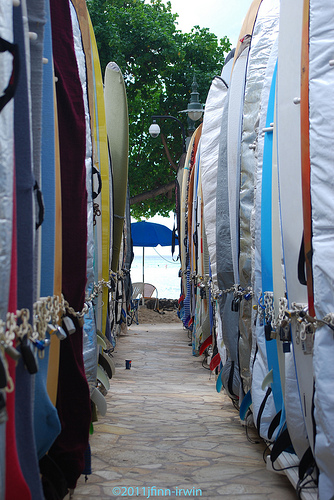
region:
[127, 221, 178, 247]
Blue beach umbrella.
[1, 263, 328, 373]
Locks locking the surfboards up.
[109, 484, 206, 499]
Copyright for jfinn-irwin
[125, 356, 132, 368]
A blue and red paper cup.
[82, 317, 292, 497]
A light stone walk way.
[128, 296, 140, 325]
A small blue chair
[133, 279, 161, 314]
Two beach chairs.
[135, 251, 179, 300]
The water of either an ocean or bay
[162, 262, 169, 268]
A person out in the water.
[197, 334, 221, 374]
Two red surfboard fins.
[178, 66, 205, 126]
Light above surfboard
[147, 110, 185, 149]
Security camera near blue umbrella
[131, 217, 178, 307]
Blue umbrella above chair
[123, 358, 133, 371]
Beverage cup on ground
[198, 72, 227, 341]
White surfboard cover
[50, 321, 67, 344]
Lock on blue surfboard cover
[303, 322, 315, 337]
Lock on white surfboard cover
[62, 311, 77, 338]
Lock on yellow surfboard cover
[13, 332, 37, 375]
Lock on red surfboard cover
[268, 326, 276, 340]
Lock on white surfboard cover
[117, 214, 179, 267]
an open blue umbrella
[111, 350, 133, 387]
cup on the ground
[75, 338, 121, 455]
fins of several surfboards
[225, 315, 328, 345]
severallocks on surfboards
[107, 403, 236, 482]
colored flattened rocks on ground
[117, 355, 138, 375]
a blua and red cup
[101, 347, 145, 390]
blue and red pepsi cup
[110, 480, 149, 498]
blue numbers that are 2011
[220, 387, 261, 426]
a blue surfboard fin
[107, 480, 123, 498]
blue letter c with circle around it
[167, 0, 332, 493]
right side row of secured surfboards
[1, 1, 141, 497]
left hand row of secured surfboards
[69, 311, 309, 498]
brown stone walk way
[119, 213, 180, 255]
dark blue beach umbrella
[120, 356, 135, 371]
dark blue paper cup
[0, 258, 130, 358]
white chain securing left hand surfboards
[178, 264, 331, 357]
white chain securing right surfboards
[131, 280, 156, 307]
white metal beach chair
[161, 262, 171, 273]
distant person in ocean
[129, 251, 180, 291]
distant blue ocean water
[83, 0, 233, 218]
A huge fully grown tree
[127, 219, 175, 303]
A blue umbrella in an open area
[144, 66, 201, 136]
Two street lighting lamps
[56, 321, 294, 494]
A long path between surf boards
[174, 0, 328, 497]
Colored surf boards on the right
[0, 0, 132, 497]
Colored surf boards on the left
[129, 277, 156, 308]
A white plastic chair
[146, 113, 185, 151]
A white street lamp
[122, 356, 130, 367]
A small container on the path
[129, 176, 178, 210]
A brown diagonal branch